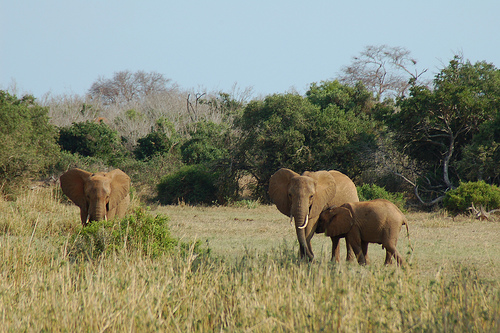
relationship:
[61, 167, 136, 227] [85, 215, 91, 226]
elephant has tusk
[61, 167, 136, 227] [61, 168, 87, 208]
elephant has a big ear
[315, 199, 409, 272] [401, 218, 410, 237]
elephant has tail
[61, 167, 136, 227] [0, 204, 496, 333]
elephant standing on field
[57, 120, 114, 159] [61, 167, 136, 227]
tree behind elephant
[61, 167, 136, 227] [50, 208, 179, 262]
elephant behind shrub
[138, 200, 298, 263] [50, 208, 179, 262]
opening by shrub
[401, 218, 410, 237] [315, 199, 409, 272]
tail of elephant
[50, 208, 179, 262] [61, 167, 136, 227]
shrub in front of elephant